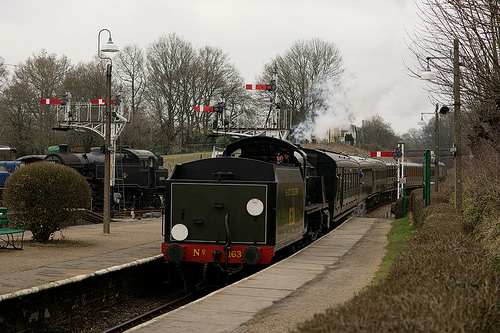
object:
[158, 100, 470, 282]
train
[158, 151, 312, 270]
car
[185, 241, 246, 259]
writing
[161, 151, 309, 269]
engine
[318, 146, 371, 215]
car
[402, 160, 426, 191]
passenger car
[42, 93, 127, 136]
traffic signal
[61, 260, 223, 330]
tracks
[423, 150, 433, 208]
post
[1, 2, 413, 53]
sky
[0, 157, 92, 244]
bush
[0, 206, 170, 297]
sidewalk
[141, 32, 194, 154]
tree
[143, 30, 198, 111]
branches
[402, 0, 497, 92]
branches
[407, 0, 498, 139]
tree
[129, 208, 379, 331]
sidewalk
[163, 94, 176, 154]
trunk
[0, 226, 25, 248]
bench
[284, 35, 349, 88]
branches